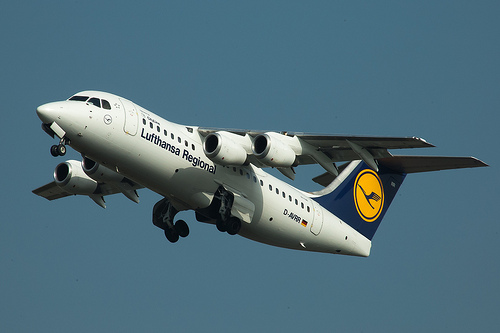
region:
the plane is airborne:
[29, 90, 489, 256]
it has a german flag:
[298, 218, 309, 227]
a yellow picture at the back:
[350, 170, 388, 220]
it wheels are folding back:
[158, 190, 205, 247]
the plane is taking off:
[28, 89, 497, 258]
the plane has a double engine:
[196, 130, 296, 170]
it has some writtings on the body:
[137, 122, 220, 177]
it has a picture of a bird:
[356, 176, 383, 207]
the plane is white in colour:
[37, 90, 490, 295]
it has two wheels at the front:
[42, 142, 74, 158]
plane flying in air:
[34, 89, 486, 259]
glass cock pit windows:
[66, 93, 110, 110]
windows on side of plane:
[137, 118, 310, 212]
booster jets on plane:
[204, 130, 298, 165]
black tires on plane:
[164, 217, 190, 244]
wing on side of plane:
[213, 125, 429, 157]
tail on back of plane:
[318, 152, 410, 233]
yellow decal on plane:
[354, 168, 384, 221]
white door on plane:
[120, 101, 140, 135]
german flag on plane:
[301, 218, 308, 225]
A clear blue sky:
[1, 0, 498, 332]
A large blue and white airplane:
[31, 87, 491, 261]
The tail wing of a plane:
[313, 153, 490, 256]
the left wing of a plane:
[203, 123, 435, 165]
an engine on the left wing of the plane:
[249, 129, 302, 165]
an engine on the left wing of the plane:
[202, 129, 247, 164]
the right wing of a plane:
[33, 158, 145, 206]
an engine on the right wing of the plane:
[53, 159, 95, 198]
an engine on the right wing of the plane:
[78, 155, 122, 184]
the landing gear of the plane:
[48, 141, 242, 243]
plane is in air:
[4, 58, 491, 325]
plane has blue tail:
[314, 169, 410, 239]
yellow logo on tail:
[343, 160, 397, 230]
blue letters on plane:
[136, 123, 222, 178]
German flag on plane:
[296, 211, 313, 233]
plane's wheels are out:
[45, 130, 245, 255]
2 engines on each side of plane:
[27, 128, 302, 199]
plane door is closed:
[113, 94, 142, 144]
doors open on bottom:
[40, 114, 67, 139]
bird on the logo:
[354, 171, 385, 213]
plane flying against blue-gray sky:
[31, 18, 487, 318]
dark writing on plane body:
[130, 125, 215, 176]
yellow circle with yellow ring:
[350, 161, 385, 221]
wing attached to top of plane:
[165, 120, 432, 165]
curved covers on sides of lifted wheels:
[147, 181, 258, 240]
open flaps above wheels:
[36, 115, 66, 155]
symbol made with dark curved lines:
[355, 175, 381, 212]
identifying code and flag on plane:
[275, 200, 310, 225]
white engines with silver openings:
[200, 121, 300, 171]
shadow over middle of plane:
[163, 125, 266, 240]